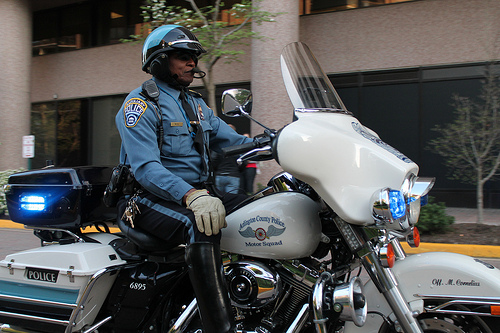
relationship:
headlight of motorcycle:
[385, 172, 430, 242] [2, 35, 492, 292]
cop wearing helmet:
[112, 23, 273, 333] [137, 18, 208, 83]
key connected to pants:
[126, 211, 135, 229] [117, 177, 208, 243]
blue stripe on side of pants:
[131, 191, 203, 244] [121, 182, 269, 313]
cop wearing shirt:
[112, 23, 273, 333] [113, 79, 273, 203]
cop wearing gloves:
[112, 23, 273, 333] [178, 182, 228, 240]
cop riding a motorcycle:
[112, 23, 273, 333] [8, 135, 483, 332]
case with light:
[7, 168, 109, 225] [19, 194, 46, 210]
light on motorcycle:
[19, 194, 46, 210] [0, 109, 498, 330]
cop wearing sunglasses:
[112, 23, 273, 333] [170, 45, 199, 64]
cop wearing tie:
[112, 23, 273, 333] [176, 90, 219, 185]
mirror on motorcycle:
[212, 79, 258, 126] [5, 22, 499, 318]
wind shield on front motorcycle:
[279, 40, 353, 115] [17, 39, 497, 330]